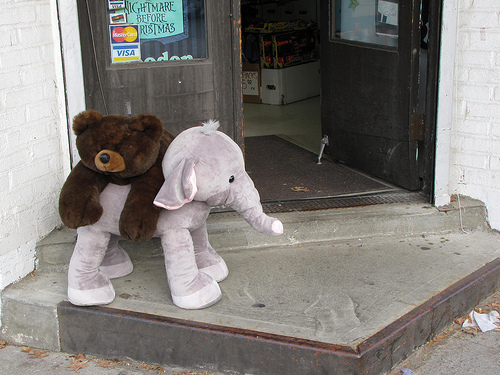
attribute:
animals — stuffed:
[57, 107, 284, 309]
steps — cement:
[0, 193, 499, 374]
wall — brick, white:
[450, 0, 498, 236]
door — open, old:
[314, 1, 424, 191]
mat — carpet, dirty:
[244, 135, 401, 203]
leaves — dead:
[424, 295, 499, 347]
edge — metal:
[59, 257, 499, 374]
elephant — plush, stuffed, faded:
[66, 119, 284, 311]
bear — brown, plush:
[59, 109, 175, 241]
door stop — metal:
[318, 135, 331, 165]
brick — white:
[1, 4, 66, 295]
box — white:
[262, 58, 322, 106]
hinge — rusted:
[408, 110, 428, 141]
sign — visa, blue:
[109, 43, 140, 65]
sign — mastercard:
[109, 23, 140, 46]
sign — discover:
[109, 11, 129, 27]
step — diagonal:
[36, 193, 491, 270]